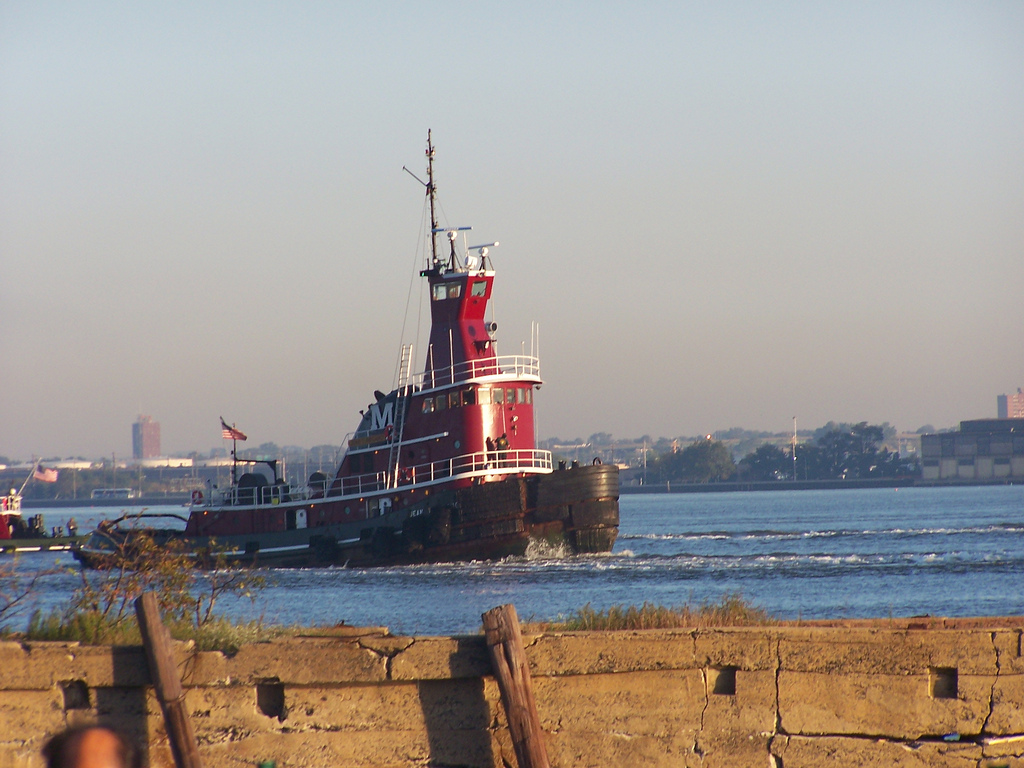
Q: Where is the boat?
A: In the harbor.